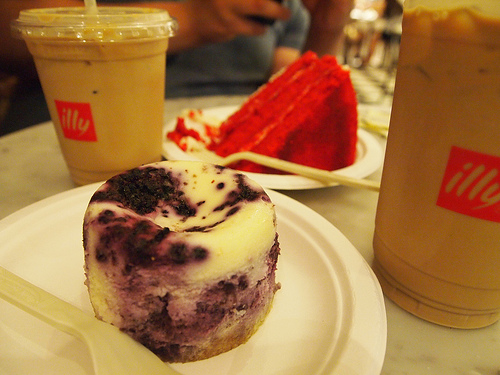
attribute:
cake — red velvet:
[219, 45, 371, 178]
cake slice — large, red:
[207, 50, 358, 175]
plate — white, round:
[1, 167, 391, 373]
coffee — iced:
[27, 31, 169, 184]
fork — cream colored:
[186, 139, 383, 196]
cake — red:
[211, 47, 356, 169]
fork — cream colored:
[1, 265, 174, 370]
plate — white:
[178, 110, 416, 219]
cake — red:
[212, 57, 362, 167]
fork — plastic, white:
[3, 269, 183, 374]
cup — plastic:
[371, 0, 498, 328]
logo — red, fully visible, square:
[49, 92, 101, 144]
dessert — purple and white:
[74, 152, 289, 359]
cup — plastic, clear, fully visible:
[7, 0, 176, 180]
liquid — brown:
[58, 48, 154, 134]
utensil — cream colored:
[3, 256, 170, 371]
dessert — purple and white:
[76, 135, 317, 368]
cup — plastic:
[16, 8, 173, 184]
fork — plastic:
[29, 293, 153, 371]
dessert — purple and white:
[70, 143, 297, 367]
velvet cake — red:
[207, 51, 357, 181]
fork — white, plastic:
[181, 136, 376, 181]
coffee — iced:
[54, 31, 188, 142]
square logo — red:
[442, 142, 494, 219]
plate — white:
[34, 167, 259, 361]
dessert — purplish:
[122, 174, 327, 356]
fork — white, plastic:
[162, 138, 380, 192]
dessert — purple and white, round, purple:
[81, 161, 279, 363]